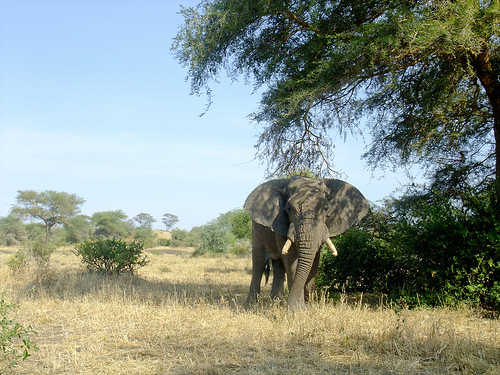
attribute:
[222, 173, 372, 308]
elephant — gray, large, wrinkled, standing, field, looking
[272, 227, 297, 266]
tusk — white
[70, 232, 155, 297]
tree — small, tall, overhanging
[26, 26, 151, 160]
sky — blue, clear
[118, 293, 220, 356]
grass — dry, dead, brown, dr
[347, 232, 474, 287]
bush — green, grass